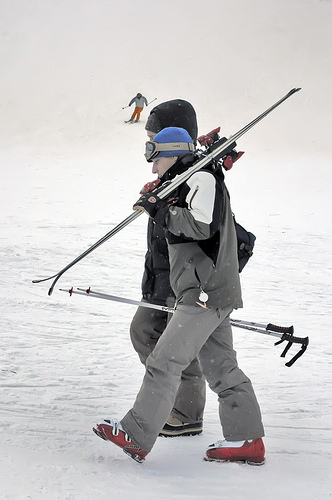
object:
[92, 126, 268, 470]
man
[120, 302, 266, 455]
pants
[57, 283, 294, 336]
ski poles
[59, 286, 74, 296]
tops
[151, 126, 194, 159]
hat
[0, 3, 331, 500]
ground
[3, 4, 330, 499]
snow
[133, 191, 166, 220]
gloves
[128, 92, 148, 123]
person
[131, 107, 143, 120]
pants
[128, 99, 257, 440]
man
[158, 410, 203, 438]
boots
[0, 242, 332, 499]
tracks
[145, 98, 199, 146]
hat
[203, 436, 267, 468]
boot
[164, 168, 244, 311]
jacket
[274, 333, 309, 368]
handle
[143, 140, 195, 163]
goggles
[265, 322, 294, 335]
handles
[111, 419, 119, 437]
clamps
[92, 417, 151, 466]
boot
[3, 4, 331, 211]
hill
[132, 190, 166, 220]
hand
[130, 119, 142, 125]
skis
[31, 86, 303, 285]
skis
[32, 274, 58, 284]
tips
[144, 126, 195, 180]
head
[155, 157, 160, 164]
eye